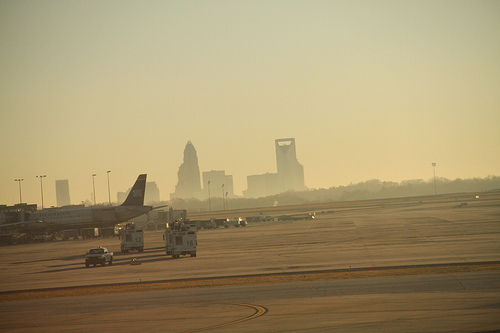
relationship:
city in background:
[156, 111, 368, 208] [5, 42, 455, 308]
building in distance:
[174, 129, 213, 206] [5, 42, 455, 308]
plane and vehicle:
[1, 158, 181, 259] [117, 222, 147, 250]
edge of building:
[192, 141, 208, 161] [174, 129, 213, 206]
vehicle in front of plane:
[117, 222, 147, 250] [1, 158, 181, 259]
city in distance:
[156, 111, 368, 208] [105, 74, 450, 232]